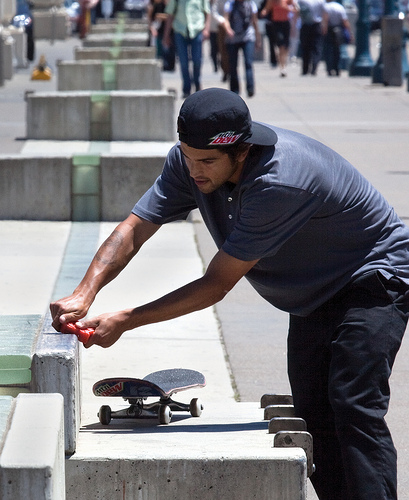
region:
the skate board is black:
[79, 347, 239, 445]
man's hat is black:
[147, 54, 272, 155]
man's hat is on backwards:
[146, 65, 282, 167]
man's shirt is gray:
[91, 104, 373, 347]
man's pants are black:
[295, 252, 408, 475]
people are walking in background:
[142, 2, 404, 97]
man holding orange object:
[49, 293, 114, 355]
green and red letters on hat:
[200, 118, 247, 154]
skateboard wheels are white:
[109, 361, 214, 439]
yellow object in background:
[27, 44, 80, 107]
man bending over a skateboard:
[35, 68, 408, 493]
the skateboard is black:
[79, 348, 218, 434]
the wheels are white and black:
[145, 400, 213, 436]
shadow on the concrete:
[87, 400, 261, 449]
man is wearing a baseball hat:
[146, 73, 278, 161]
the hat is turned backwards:
[153, 69, 269, 169]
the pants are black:
[272, 262, 399, 479]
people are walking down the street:
[129, 5, 356, 97]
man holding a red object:
[25, 280, 135, 354]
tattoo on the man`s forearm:
[56, 214, 134, 274]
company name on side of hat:
[201, 124, 249, 143]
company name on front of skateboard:
[85, 374, 127, 399]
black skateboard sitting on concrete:
[94, 363, 217, 432]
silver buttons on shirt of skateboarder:
[223, 194, 237, 224]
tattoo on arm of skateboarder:
[74, 221, 138, 280]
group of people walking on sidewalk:
[145, 0, 352, 94]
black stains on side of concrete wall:
[65, 460, 228, 498]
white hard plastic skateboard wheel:
[186, 395, 219, 422]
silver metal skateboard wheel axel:
[106, 396, 159, 424]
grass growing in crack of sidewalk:
[222, 357, 244, 406]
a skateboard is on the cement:
[88, 361, 208, 434]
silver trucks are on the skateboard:
[94, 397, 203, 427]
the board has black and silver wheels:
[94, 398, 204, 424]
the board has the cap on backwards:
[174, 85, 279, 153]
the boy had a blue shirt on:
[122, 127, 408, 316]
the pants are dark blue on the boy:
[284, 269, 407, 494]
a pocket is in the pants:
[369, 262, 408, 318]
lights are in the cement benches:
[3, 11, 136, 452]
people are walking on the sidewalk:
[70, 1, 407, 97]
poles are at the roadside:
[350, 3, 407, 84]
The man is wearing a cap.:
[169, 76, 278, 150]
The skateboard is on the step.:
[83, 359, 206, 439]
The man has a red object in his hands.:
[57, 307, 102, 346]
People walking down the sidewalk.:
[169, 9, 333, 74]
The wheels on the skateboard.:
[151, 398, 218, 424]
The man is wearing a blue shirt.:
[215, 201, 374, 287]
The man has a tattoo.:
[76, 222, 135, 265]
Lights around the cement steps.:
[62, 155, 103, 250]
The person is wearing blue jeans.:
[221, 42, 256, 101]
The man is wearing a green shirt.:
[157, 7, 206, 37]